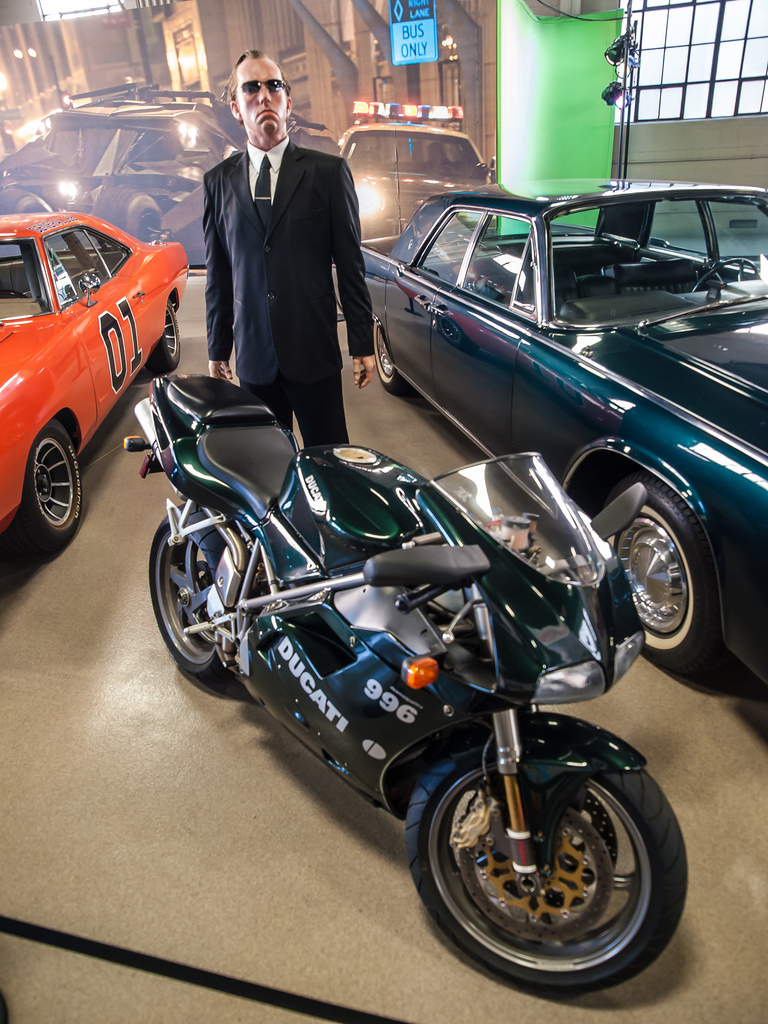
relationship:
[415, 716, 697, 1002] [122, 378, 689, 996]
tire of bike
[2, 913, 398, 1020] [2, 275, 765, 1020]
stripe on floor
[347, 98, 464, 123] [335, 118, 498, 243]
police lights on top of car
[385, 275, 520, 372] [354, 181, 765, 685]
reflection on car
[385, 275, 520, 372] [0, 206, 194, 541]
reflection of car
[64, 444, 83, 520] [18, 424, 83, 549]
letterings on side of wheel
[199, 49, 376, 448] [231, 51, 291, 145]
man has face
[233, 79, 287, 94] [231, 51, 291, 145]
sunglasses on face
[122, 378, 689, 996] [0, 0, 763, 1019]
bike in garage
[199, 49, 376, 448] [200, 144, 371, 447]
man wearing suit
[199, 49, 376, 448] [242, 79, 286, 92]
man wearing sunglasses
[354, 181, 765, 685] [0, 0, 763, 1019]
car sitting in garage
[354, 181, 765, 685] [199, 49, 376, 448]
car next to man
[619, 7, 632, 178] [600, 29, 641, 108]
pole holding lights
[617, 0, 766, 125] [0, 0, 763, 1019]
windows high in garage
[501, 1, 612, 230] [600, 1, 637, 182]
green screen next to lights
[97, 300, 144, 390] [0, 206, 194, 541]
number written on side of car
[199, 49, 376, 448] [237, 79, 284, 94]
man wearing sunglasses